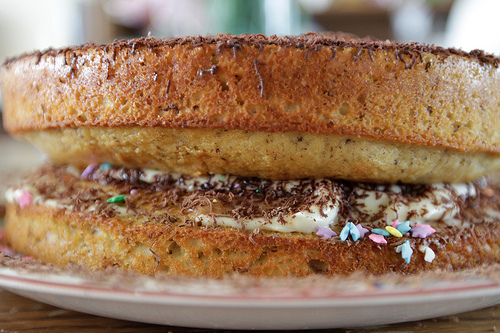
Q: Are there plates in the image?
A: Yes, there is a plate.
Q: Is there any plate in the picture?
A: Yes, there is a plate.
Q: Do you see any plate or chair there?
A: Yes, there is a plate.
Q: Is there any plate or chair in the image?
A: Yes, there is a plate.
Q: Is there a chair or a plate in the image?
A: Yes, there is a plate.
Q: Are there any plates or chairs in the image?
A: Yes, there is a plate.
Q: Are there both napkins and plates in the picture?
A: No, there is a plate but no napkins.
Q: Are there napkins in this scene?
A: No, there are no napkins.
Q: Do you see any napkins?
A: No, there are no napkins.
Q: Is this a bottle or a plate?
A: This is a plate.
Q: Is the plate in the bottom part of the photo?
A: Yes, the plate is in the bottom of the image.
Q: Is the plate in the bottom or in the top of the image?
A: The plate is in the bottom of the image.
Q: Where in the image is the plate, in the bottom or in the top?
A: The plate is in the bottom of the image.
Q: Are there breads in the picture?
A: Yes, there is a bread.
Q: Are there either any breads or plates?
A: Yes, there is a bread.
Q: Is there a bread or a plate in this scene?
A: Yes, there is a bread.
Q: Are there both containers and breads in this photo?
A: No, there is a bread but no containers.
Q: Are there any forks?
A: No, there are no forks.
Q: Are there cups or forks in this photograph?
A: No, there are no forks or cups.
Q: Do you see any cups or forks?
A: No, there are no forks or cups.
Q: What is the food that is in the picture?
A: The food is a bread.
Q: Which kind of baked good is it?
A: The food is a bread.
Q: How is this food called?
A: This is a bread.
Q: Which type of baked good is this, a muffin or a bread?
A: This is a bread.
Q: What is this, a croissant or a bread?
A: This is a bread.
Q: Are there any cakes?
A: Yes, there is a cake.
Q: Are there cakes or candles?
A: Yes, there is a cake.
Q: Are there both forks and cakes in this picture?
A: No, there is a cake but no forks.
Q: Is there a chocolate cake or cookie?
A: Yes, there is a chocolate cake.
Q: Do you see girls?
A: No, there are no girls.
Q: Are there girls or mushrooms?
A: No, there are no girls or mushrooms.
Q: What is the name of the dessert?
A: The dessert is a cake.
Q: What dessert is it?
A: The dessert is a cake.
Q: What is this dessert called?
A: This is a cake.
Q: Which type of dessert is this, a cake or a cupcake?
A: This is a cake.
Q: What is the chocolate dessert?
A: The dessert is a cake.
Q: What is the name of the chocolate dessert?
A: The dessert is a cake.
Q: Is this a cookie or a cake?
A: This is a cake.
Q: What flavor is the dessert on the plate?
A: This is a chocolate cake.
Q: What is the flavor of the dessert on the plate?
A: This is a chocolate cake.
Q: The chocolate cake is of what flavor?
A: This is a chocolate cake.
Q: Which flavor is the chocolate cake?
A: This is a chocolate cake.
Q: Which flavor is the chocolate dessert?
A: This is a chocolate cake.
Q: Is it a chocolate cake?
A: Yes, this is a chocolate cake.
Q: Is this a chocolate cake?
A: Yes, this is a chocolate cake.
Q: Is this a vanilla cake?
A: No, this is a chocolate cake.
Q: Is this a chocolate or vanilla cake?
A: This is a chocolate cake.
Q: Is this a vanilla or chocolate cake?
A: This is a chocolate cake.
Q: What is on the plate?
A: The cake is on the plate.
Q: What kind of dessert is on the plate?
A: The dessert is a cake.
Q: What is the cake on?
A: The cake is on the plate.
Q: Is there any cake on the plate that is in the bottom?
A: Yes, there is a cake on the plate.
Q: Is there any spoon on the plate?
A: No, there is a cake on the plate.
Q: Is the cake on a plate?
A: Yes, the cake is on a plate.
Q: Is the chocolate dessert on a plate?
A: Yes, the cake is on a plate.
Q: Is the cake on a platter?
A: No, the cake is on a plate.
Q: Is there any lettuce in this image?
A: No, there is no lettuce.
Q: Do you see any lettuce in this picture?
A: No, there is no lettuce.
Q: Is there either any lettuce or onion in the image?
A: No, there are no lettuce or onions.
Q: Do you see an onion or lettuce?
A: No, there are no lettuce or onions.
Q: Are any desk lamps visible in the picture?
A: No, there are no desk lamps.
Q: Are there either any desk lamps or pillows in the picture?
A: No, there are no desk lamps or pillows.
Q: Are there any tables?
A: Yes, there is a table.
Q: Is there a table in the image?
A: Yes, there is a table.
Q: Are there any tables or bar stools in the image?
A: Yes, there is a table.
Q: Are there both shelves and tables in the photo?
A: No, there is a table but no shelves.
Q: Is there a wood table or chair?
A: Yes, there is a wood table.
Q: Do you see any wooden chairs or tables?
A: Yes, there is a wood table.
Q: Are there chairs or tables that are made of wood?
A: Yes, the table is made of wood.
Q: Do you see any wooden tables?
A: Yes, there is a wood table.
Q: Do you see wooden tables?
A: Yes, there is a wood table.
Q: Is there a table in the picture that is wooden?
A: Yes, there is a table that is wooden.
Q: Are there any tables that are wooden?
A: Yes, there is a table that is wooden.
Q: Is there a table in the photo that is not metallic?
A: Yes, there is a wooden table.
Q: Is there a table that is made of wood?
A: Yes, there is a table that is made of wood.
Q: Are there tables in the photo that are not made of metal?
A: Yes, there is a table that is made of wood.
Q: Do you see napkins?
A: No, there are no napkins.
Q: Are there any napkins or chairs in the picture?
A: No, there are no napkins or chairs.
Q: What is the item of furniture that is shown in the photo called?
A: The piece of furniture is a table.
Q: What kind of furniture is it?
A: The piece of furniture is a table.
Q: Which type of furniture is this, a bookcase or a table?
A: That is a table.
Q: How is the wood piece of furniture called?
A: The piece of furniture is a table.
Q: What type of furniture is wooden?
A: The furniture is a table.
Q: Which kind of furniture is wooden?
A: The furniture is a table.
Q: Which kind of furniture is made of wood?
A: The furniture is a table.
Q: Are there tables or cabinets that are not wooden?
A: No, there is a table but it is wooden.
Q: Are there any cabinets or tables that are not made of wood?
A: No, there is a table but it is made of wood.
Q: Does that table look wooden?
A: Yes, the table is wooden.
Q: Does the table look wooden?
A: Yes, the table is wooden.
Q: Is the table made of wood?
A: Yes, the table is made of wood.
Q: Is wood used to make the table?
A: Yes, the table is made of wood.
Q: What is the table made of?
A: The table is made of wood.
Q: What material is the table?
A: The table is made of wood.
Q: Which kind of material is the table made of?
A: The table is made of wood.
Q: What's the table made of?
A: The table is made of wood.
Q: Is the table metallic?
A: No, the table is wooden.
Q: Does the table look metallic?
A: No, the table is wooden.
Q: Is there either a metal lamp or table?
A: No, there is a table but it is wooden.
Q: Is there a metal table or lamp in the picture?
A: No, there is a table but it is wooden.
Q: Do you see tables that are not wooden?
A: No, there is a table but it is wooden.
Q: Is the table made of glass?
A: No, the table is made of wood.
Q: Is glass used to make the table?
A: No, the table is made of wood.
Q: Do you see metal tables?
A: No, there is a table but it is made of wood.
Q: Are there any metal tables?
A: No, there is a table but it is made of wood.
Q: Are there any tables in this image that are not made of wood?
A: No, there is a table but it is made of wood.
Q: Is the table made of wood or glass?
A: The table is made of wood.